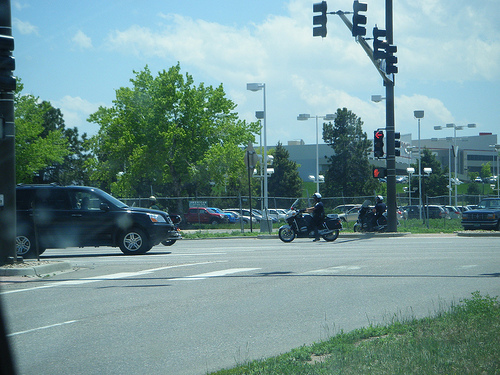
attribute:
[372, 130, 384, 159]
streetlight — red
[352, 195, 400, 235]
motorcycle — black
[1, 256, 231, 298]
line — white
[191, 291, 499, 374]
grass — uncut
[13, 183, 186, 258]
suv — dark, moving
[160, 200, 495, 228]
parking lot — fenced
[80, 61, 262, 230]
tree — bushy, leafy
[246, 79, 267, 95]
light — white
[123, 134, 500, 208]
building — large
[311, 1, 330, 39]
streetlight — hanging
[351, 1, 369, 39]
streetlight — hanging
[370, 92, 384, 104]
light — white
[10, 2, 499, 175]
sky — clear, blue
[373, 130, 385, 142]
light — red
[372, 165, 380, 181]
hand — red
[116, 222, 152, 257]
tire — black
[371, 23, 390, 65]
streetlight — hanging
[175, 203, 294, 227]
cars — parked